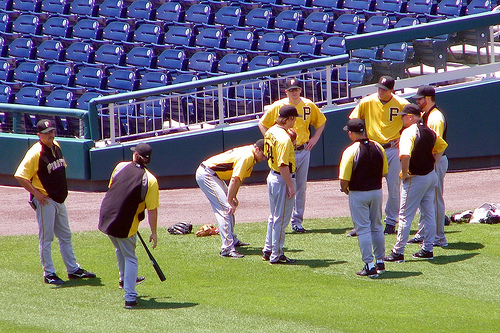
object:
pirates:
[19, 55, 467, 286]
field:
[13, 227, 425, 330]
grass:
[30, 230, 500, 310]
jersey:
[267, 127, 311, 177]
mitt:
[165, 212, 195, 247]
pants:
[200, 156, 253, 246]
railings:
[115, 62, 363, 133]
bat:
[135, 231, 169, 299]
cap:
[287, 70, 304, 94]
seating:
[56, 14, 214, 51]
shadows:
[282, 222, 332, 280]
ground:
[114, 171, 436, 308]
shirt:
[264, 131, 298, 177]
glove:
[168, 221, 207, 242]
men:
[184, 112, 271, 258]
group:
[33, 110, 431, 250]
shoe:
[44, 264, 64, 313]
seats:
[227, 14, 327, 51]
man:
[33, 116, 78, 291]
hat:
[278, 100, 310, 129]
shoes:
[66, 266, 101, 281]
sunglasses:
[46, 127, 54, 136]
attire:
[25, 145, 75, 260]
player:
[230, 108, 314, 248]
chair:
[193, 20, 235, 70]